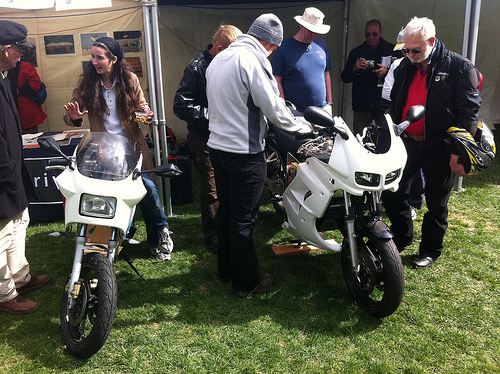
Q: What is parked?
A: Motorcycles.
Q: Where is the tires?
A: On the ground.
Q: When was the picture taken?
A: Daytime.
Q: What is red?
A: Man on rights shirt.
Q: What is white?
A: Motorcycles.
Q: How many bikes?
A: Two.